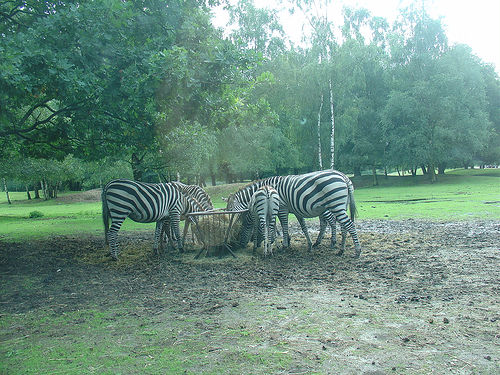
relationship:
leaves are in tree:
[0, 1, 240, 164] [0, 2, 252, 168]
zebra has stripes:
[100, 179, 211, 263] [110, 185, 173, 215]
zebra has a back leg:
[221, 168, 363, 259] [333, 208, 363, 257]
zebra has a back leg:
[221, 168, 363, 259] [336, 214, 349, 259]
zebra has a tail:
[100, 179, 211, 263] [100, 189, 111, 240]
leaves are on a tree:
[0, 1, 240, 164] [0, 2, 252, 168]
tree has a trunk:
[371, 45, 497, 185] [424, 163, 437, 185]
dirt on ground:
[4, 219, 499, 342] [2, 168, 499, 375]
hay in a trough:
[199, 213, 240, 248] [187, 207, 252, 259]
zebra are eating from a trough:
[222, 169, 362, 259] [187, 207, 252, 259]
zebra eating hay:
[100, 179, 211, 263] [199, 213, 240, 248]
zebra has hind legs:
[100, 179, 211, 263] [104, 212, 128, 262]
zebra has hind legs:
[236, 183, 281, 258] [256, 210, 277, 259]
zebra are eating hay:
[222, 169, 362, 259] [199, 213, 240, 248]